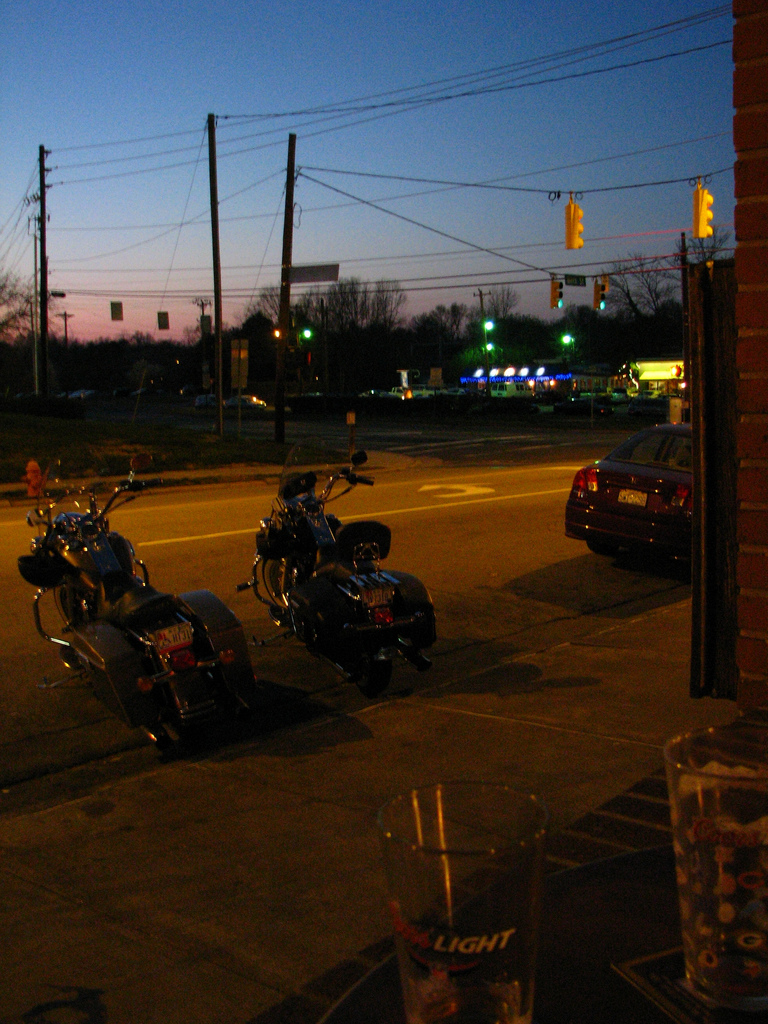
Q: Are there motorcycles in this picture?
A: Yes, there are motorcycles.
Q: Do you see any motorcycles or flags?
A: Yes, there are motorcycles.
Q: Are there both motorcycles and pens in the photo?
A: No, there are motorcycles but no pens.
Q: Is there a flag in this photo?
A: No, there are no flags.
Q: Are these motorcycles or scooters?
A: These are motorcycles.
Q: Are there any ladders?
A: No, there are no ladders.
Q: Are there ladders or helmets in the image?
A: No, there are no ladders or helmets.